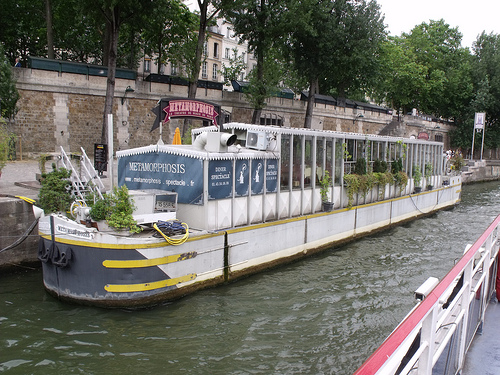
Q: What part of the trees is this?
A: Branches.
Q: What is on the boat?
A: Green vegetation.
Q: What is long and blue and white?
A: A boat.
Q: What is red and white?
A: A fence.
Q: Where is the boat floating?
A: On water.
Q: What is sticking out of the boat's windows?
A: Plants.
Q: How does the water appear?
A: Calm.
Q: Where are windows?
A: On a building.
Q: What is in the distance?
A: Buildings.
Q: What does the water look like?
A: Murky.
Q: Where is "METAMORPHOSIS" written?
A: On front of the boat.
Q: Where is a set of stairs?
A: Next to the boat.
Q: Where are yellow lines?
A: On front of boat.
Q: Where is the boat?
A: On the water.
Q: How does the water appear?
A: Calm.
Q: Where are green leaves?
A: On trees.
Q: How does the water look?
A: Murky.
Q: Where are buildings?
A: Behind the trees.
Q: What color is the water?
A: Murky brown.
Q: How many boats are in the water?
A: One.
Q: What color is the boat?
A: White,yellow, and blue.